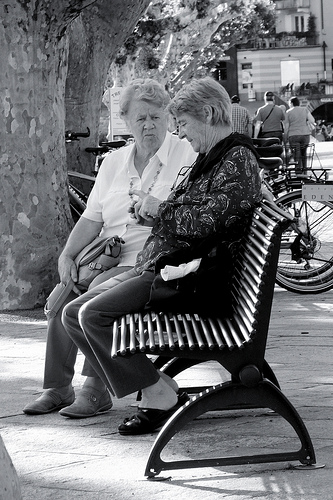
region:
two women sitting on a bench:
[46, 74, 277, 371]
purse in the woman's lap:
[60, 227, 125, 295]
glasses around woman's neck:
[169, 163, 204, 202]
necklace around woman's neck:
[117, 162, 167, 201]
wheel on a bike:
[286, 196, 330, 296]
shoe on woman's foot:
[68, 383, 103, 411]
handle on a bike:
[60, 124, 86, 152]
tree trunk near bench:
[0, 52, 78, 238]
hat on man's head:
[263, 90, 274, 100]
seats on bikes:
[255, 132, 288, 176]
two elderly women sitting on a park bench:
[20, 73, 264, 438]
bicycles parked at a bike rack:
[267, 153, 331, 299]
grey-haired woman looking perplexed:
[111, 75, 174, 153]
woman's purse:
[50, 230, 137, 295]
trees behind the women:
[0, 0, 241, 309]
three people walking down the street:
[227, 88, 317, 176]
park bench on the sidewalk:
[108, 190, 320, 481]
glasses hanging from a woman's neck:
[166, 157, 216, 195]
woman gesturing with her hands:
[126, 67, 266, 252]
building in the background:
[227, 0, 331, 118]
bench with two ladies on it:
[108, 198, 318, 479]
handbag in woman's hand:
[40, 233, 128, 315]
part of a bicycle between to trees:
[63, 127, 124, 215]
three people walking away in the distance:
[229, 88, 317, 176]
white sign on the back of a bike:
[298, 179, 331, 199]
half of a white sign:
[107, 84, 131, 140]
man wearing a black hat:
[262, 88, 275, 99]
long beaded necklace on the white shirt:
[128, 163, 162, 203]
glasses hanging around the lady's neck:
[169, 158, 199, 192]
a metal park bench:
[108, 199, 322, 476]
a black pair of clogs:
[108, 379, 198, 445]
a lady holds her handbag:
[21, 77, 177, 420]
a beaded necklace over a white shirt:
[120, 153, 164, 205]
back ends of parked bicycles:
[258, 127, 332, 303]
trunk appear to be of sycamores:
[0, 3, 127, 314]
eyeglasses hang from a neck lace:
[163, 160, 209, 195]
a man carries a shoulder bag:
[251, 89, 283, 157]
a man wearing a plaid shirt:
[223, 90, 251, 138]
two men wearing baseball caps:
[226, 86, 277, 106]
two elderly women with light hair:
[86, 78, 245, 195]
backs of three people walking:
[229, 91, 323, 144]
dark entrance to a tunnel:
[307, 93, 332, 144]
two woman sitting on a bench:
[55, 75, 289, 485]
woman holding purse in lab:
[54, 78, 165, 331]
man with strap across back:
[251, 87, 289, 139]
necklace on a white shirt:
[126, 147, 176, 190]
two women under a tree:
[8, 8, 264, 185]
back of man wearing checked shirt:
[230, 92, 254, 135]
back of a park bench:
[239, 206, 324, 475]